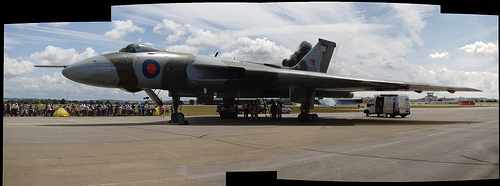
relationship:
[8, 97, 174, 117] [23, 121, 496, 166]
people on runway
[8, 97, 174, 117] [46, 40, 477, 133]
people near jet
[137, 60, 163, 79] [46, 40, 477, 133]
bullseye on jet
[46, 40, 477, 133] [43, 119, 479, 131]
jet has shadow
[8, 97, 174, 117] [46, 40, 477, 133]
people watching jet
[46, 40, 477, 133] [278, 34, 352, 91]
jet has tail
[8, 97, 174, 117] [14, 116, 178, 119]
people behind fence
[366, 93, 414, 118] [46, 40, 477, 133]
van behind jet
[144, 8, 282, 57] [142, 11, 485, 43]
clouds in sky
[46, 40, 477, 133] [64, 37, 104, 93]
jet has nose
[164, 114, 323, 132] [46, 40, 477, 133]
wheels on jet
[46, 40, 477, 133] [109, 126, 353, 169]
jet on cement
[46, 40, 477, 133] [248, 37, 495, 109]
jet has wing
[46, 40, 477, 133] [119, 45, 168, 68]
jet has cockpit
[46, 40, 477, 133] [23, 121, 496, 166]
jet on runway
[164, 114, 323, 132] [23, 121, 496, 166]
wheels on runway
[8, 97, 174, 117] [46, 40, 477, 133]
people under jet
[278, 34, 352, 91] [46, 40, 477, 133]
tail on jet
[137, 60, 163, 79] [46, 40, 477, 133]
bullseye painted on jet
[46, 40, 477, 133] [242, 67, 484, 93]
jet has wing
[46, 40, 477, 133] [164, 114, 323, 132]
jet has wheels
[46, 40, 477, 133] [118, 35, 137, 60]
jet has window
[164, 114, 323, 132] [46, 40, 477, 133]
wheels under jet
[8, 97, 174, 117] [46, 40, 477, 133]
people next to jet